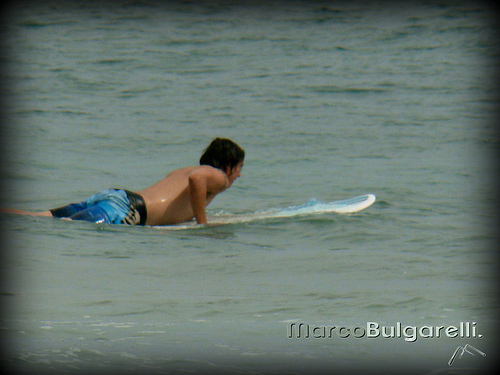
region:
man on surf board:
[81, 124, 301, 257]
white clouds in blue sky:
[27, 10, 106, 79]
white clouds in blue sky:
[55, 68, 116, 125]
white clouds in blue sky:
[58, 225, 143, 290]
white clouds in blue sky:
[223, 262, 276, 300]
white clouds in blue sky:
[390, 211, 461, 279]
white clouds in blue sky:
[254, 71, 331, 136]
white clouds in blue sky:
[355, 73, 453, 146]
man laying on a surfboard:
[13, 103, 407, 242]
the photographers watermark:
[280, 308, 488, 350]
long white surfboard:
[149, 182, 386, 233]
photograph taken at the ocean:
[7, 11, 485, 258]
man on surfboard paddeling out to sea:
[35, 121, 397, 231]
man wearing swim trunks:
[40, 178, 150, 240]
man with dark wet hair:
[178, 116, 256, 188]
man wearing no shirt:
[25, 102, 277, 239]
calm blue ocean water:
[58, 45, 371, 132]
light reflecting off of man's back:
[135, 190, 175, 212]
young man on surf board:
[44, 129, 369, 260]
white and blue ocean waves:
[38, 25, 107, 96]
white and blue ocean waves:
[39, 106, 81, 132]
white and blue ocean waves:
[84, 259, 177, 300]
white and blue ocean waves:
[176, 232, 222, 282]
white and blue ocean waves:
[74, 311, 162, 347]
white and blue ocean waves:
[277, 254, 340, 296]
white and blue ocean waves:
[377, 87, 407, 120]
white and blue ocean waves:
[222, 63, 295, 115]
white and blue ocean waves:
[89, 86, 146, 147]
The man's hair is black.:
[200, 130, 244, 170]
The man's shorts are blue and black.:
[54, 186, 150, 227]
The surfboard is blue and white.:
[325, 199, 374, 210]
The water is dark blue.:
[125, 28, 219, 64]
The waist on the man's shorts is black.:
[126, 191, 146, 216]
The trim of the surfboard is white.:
[348, 204, 366, 213]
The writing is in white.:
[366, 322, 482, 341]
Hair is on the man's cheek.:
[203, 133, 244, 171]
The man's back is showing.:
[149, 189, 183, 214]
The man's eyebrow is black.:
[236, 161, 247, 170]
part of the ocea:
[358, 202, 368, 226]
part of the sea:
[254, 233, 280, 270]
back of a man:
[157, 183, 164, 197]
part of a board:
[317, 205, 324, 210]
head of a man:
[226, 147, 233, 160]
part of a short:
[105, 204, 112, 213]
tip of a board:
[368, 186, 383, 203]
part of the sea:
[326, 144, 340, 170]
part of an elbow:
[193, 170, 203, 177]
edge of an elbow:
[189, 169, 193, 176]